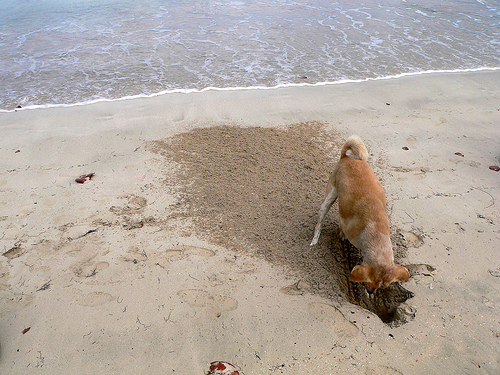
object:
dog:
[307, 134, 411, 304]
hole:
[358, 294, 414, 331]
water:
[1, 3, 499, 107]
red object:
[205, 358, 243, 374]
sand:
[12, 74, 497, 373]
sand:
[207, 128, 315, 231]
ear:
[349, 260, 370, 283]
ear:
[392, 265, 412, 284]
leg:
[306, 184, 339, 250]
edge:
[0, 67, 498, 114]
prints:
[173, 286, 241, 315]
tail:
[340, 134, 370, 162]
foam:
[194, 83, 221, 94]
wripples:
[64, 17, 213, 57]